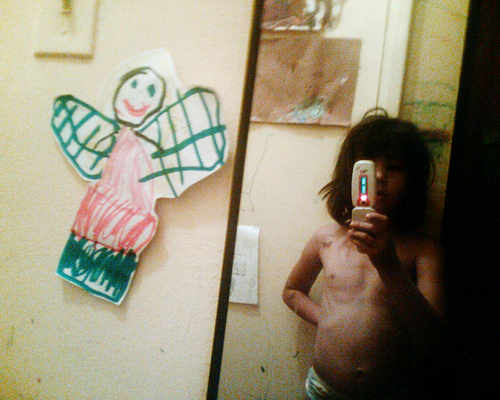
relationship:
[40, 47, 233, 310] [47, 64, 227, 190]
paper drawing of a angel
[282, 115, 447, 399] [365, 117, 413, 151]
child with hair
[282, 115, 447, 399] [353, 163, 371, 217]
child looking at cellphone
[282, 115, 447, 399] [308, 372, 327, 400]
child in underware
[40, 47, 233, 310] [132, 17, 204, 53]
paper drawing on wall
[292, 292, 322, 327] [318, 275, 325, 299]
arm behind back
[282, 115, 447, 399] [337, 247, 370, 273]
child bare chest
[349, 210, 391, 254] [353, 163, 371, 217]
hand holding cellphone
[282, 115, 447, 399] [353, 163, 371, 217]
child holding cellphone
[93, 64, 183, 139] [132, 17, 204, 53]
drawing on wall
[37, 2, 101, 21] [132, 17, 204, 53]
partial light switch on wall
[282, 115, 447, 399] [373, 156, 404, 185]
child taking a picture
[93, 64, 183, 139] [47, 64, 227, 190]
drawing of an angel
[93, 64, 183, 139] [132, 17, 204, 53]
drawing hanging on wall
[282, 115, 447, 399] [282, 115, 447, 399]
child taking a child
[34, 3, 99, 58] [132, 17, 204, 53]
light switch on wall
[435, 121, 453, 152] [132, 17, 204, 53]
marks on wall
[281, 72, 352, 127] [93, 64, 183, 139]
paper has a drawing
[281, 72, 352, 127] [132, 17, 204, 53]
paper on wall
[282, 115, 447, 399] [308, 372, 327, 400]
child wearing underware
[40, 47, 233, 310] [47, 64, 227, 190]
paper drawing of an angel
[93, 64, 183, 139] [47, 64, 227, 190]
drawing of a angel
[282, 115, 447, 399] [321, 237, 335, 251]
child has tattoo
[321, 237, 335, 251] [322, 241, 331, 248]
tattoo of a butterfly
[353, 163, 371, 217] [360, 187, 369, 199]
cellphone with lights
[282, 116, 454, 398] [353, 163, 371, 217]
child using cellphone